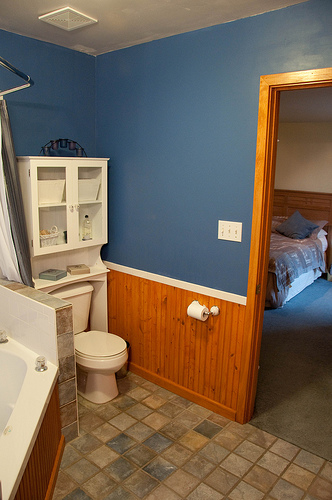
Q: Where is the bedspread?
A: On bed.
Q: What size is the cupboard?
A: Big.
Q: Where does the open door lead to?
A: Bedroom.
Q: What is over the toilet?
A: A white shelf.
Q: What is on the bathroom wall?
A: Blue paint.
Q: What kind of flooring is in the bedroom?
A: Carpet.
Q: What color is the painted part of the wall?
A: Blue.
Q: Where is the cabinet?
A: Above the toilet.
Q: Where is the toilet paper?
A: On the wood panel wall.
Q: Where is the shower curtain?
A: By the toilet.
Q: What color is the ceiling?
A: White.